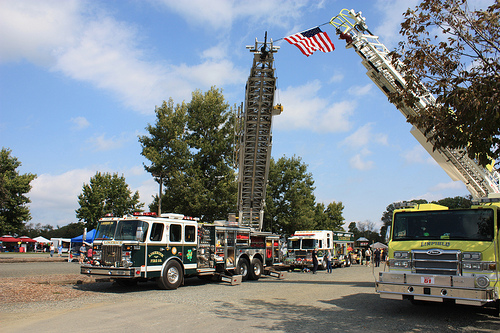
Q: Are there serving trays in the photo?
A: No, there are no serving trays.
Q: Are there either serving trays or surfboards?
A: No, there are no serving trays or surfboards.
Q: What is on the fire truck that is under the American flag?
A: The ladder is on the fire truck.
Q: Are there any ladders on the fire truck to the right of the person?
A: Yes, there is a ladder on the fire truck.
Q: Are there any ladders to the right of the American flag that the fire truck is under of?
A: Yes, there is a ladder to the right of the American flag.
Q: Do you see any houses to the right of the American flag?
A: No, there is a ladder to the right of the American flag.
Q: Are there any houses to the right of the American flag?
A: No, there is a ladder to the right of the American flag.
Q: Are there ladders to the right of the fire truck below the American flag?
A: Yes, there is a ladder to the right of the fire truck.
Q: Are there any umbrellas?
A: No, there are no umbrellas.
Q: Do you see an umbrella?
A: No, there are no umbrellas.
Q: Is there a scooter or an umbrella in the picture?
A: No, there are no umbrellas or scooters.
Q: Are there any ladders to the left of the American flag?
A: Yes, there is a ladder to the left of the American flag.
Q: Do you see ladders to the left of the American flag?
A: Yes, there is a ladder to the left of the American flag.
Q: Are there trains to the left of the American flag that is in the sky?
A: No, there is a ladder to the left of the American flag.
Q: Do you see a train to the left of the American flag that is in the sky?
A: No, there is a ladder to the left of the American flag.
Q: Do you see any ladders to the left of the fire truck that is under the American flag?
A: Yes, there is a ladder to the left of the fire truck.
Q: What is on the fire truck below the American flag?
A: The ladder is on the fire truck.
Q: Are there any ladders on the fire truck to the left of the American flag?
A: Yes, there is a ladder on the fire truck.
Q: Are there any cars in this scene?
A: No, there are no cars.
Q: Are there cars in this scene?
A: No, there are no cars.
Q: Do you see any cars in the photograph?
A: No, there are no cars.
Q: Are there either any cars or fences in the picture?
A: No, there are no cars or fences.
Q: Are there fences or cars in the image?
A: No, there are no cars or fences.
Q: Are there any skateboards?
A: No, there are no skateboards.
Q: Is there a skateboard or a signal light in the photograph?
A: No, there are no skateboards or traffic lights.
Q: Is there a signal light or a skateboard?
A: No, there are no skateboards or traffic lights.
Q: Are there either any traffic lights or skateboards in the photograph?
A: No, there are no skateboards or traffic lights.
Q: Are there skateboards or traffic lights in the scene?
A: No, there are no skateboards or traffic lights.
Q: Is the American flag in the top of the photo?
A: Yes, the American flag is in the top of the image.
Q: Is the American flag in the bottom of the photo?
A: No, the American flag is in the top of the image.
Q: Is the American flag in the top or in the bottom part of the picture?
A: The American flag is in the top of the image.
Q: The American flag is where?
A: The American flag is in the sky.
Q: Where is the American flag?
A: The American flag is in the sky.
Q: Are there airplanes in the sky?
A: No, there is an American flag in the sky.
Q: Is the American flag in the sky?
A: Yes, the American flag is in the sky.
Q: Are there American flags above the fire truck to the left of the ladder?
A: Yes, there is an American flag above the fire truck.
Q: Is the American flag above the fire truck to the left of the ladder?
A: Yes, the American flag is above the fire truck.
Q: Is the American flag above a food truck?
A: No, the American flag is above the fire truck.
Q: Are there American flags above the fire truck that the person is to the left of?
A: Yes, there is an American flag above the fire truck.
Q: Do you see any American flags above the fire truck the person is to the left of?
A: Yes, there is an American flag above the fire truck.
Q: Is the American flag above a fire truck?
A: Yes, the American flag is above a fire truck.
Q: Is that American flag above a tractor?
A: No, the American flag is above a fire truck.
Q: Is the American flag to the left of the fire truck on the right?
A: Yes, the American flag is to the left of the fire truck.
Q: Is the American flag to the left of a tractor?
A: No, the American flag is to the left of the fire truck.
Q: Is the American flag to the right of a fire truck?
A: Yes, the American flag is to the right of a fire truck.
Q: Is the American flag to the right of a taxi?
A: No, the American flag is to the right of a fire truck.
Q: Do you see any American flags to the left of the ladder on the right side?
A: Yes, there is an American flag to the left of the ladder.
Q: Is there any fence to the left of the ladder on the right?
A: No, there is an American flag to the left of the ladder.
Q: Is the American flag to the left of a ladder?
A: Yes, the American flag is to the left of a ladder.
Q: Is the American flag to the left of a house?
A: No, the American flag is to the left of a ladder.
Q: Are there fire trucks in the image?
A: Yes, there is a fire truck.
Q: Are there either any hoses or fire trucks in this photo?
A: Yes, there is a fire truck.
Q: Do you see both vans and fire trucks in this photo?
A: No, there is a fire truck but no vans.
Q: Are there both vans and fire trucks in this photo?
A: No, there is a fire truck but no vans.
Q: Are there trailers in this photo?
A: No, there are no trailers.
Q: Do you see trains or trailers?
A: No, there are no trailers or trains.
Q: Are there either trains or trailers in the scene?
A: No, there are no trailers or trains.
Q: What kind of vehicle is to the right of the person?
A: The vehicle is a fire truck.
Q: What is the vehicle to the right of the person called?
A: The vehicle is a fire truck.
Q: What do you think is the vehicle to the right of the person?
A: The vehicle is a fire truck.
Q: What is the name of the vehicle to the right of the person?
A: The vehicle is a fire truck.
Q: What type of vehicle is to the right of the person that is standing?
A: The vehicle is a fire truck.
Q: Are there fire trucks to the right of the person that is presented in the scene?
A: Yes, there is a fire truck to the right of the person.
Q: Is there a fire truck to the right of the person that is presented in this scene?
A: Yes, there is a fire truck to the right of the person.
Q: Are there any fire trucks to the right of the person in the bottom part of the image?
A: Yes, there is a fire truck to the right of the person.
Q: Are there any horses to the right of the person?
A: No, there is a fire truck to the right of the person.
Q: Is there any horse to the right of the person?
A: No, there is a fire truck to the right of the person.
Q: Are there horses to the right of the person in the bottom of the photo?
A: No, there is a fire truck to the right of the person.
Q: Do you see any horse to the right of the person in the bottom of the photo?
A: No, there is a fire truck to the right of the person.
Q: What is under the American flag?
A: The fire truck is under the American flag.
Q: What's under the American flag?
A: The fire truck is under the American flag.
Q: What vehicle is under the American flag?
A: The vehicle is a fire truck.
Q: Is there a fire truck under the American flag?
A: Yes, there is a fire truck under the American flag.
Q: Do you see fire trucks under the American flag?
A: Yes, there is a fire truck under the American flag.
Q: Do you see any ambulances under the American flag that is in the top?
A: No, there is a fire truck under the American flag.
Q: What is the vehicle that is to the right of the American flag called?
A: The vehicle is a fire truck.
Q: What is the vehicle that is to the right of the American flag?
A: The vehicle is a fire truck.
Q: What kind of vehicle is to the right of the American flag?
A: The vehicle is a fire truck.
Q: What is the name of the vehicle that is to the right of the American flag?
A: The vehicle is a fire truck.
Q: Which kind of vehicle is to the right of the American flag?
A: The vehicle is a fire truck.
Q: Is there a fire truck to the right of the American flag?
A: Yes, there is a fire truck to the right of the American flag.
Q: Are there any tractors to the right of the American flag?
A: No, there is a fire truck to the right of the American flag.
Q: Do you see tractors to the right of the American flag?
A: No, there is a fire truck to the right of the American flag.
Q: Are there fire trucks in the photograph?
A: Yes, there is a fire truck.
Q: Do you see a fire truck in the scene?
A: Yes, there is a fire truck.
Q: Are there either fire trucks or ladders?
A: Yes, there is a fire truck.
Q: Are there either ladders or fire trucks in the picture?
A: Yes, there is a fire truck.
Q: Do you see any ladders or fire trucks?
A: Yes, there is a fire truck.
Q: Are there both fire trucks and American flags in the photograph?
A: Yes, there are both a fire truck and an American flag.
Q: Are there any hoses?
A: No, there are no hoses.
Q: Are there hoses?
A: No, there are no hoses.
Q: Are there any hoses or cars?
A: No, there are no hoses or cars.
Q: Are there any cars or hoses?
A: No, there are no hoses or cars.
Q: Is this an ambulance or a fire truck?
A: This is a fire truck.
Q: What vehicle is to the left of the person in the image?
A: The vehicle is a fire truck.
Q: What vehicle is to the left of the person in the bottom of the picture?
A: The vehicle is a fire truck.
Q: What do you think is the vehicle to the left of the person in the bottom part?
A: The vehicle is a fire truck.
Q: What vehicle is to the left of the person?
A: The vehicle is a fire truck.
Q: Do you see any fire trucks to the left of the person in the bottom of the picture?
A: Yes, there is a fire truck to the left of the person.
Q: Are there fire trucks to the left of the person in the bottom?
A: Yes, there is a fire truck to the left of the person.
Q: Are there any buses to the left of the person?
A: No, there is a fire truck to the left of the person.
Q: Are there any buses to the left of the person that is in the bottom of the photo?
A: No, there is a fire truck to the left of the person.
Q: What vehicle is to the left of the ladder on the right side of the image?
A: The vehicle is a fire truck.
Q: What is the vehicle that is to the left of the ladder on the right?
A: The vehicle is a fire truck.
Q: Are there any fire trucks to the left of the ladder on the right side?
A: Yes, there is a fire truck to the left of the ladder.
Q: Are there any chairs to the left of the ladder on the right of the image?
A: No, there is a fire truck to the left of the ladder.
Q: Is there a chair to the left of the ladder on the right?
A: No, there is a fire truck to the left of the ladder.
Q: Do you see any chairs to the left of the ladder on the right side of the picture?
A: No, there is a fire truck to the left of the ladder.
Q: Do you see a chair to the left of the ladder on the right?
A: No, there is a fire truck to the left of the ladder.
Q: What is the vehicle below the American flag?
A: The vehicle is a fire truck.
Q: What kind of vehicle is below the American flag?
A: The vehicle is a fire truck.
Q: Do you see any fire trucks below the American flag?
A: Yes, there is a fire truck below the American flag.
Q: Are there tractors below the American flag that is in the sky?
A: No, there is a fire truck below the American flag.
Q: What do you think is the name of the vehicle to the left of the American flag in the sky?
A: The vehicle is a fire truck.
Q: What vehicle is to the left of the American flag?
A: The vehicle is a fire truck.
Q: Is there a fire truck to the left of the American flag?
A: Yes, there is a fire truck to the left of the American flag.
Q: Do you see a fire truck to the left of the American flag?
A: Yes, there is a fire truck to the left of the American flag.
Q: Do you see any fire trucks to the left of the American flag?
A: Yes, there is a fire truck to the left of the American flag.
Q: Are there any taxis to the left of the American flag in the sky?
A: No, there is a fire truck to the left of the American flag.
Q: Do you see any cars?
A: No, there are no cars.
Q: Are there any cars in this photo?
A: No, there are no cars.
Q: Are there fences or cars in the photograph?
A: No, there are no cars or fences.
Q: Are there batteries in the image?
A: No, there are no batteries.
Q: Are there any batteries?
A: No, there are no batteries.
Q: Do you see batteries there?
A: No, there are no batteries.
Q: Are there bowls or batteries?
A: No, there are no batteries or bowls.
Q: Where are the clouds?
A: The clouds are in the sky.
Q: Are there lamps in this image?
A: No, there are no lamps.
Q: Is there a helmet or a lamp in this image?
A: No, there are no lamps or helmets.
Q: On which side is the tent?
A: The tent is on the left of the image.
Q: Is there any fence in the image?
A: No, there are no fences.